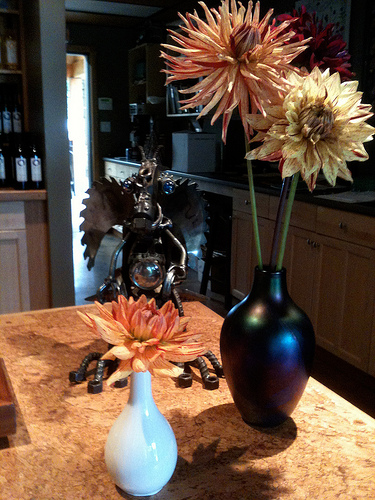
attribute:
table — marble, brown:
[1, 300, 373, 497]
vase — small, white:
[103, 369, 177, 495]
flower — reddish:
[60, 290, 205, 386]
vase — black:
[215, 261, 318, 438]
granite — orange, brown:
[217, 439, 370, 477]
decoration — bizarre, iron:
[61, 90, 234, 396]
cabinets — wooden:
[307, 222, 372, 361]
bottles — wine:
[5, 35, 43, 178]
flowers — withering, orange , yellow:
[151, 0, 372, 190]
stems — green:
[231, 122, 297, 290]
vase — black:
[219, 264, 323, 435]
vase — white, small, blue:
[103, 367, 186, 496]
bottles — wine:
[9, 149, 43, 186]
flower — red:
[275, 12, 347, 85]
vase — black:
[221, 260, 321, 425]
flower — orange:
[81, 287, 212, 391]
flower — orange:
[76, 288, 208, 384]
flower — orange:
[76, 287, 200, 390]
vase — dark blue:
[213, 156, 316, 435]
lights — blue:
[157, 186, 176, 198]